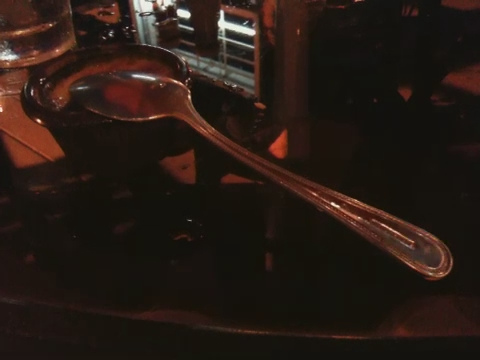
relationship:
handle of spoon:
[247, 145, 459, 286] [285, 172, 372, 221]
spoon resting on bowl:
[61, 61, 479, 285] [64, 51, 173, 68]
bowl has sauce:
[64, 51, 173, 68] [63, 65, 122, 70]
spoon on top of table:
[61, 61, 479, 285] [30, 139, 66, 158]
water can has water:
[1, 7, 74, 56] [10, 30, 49, 57]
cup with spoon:
[72, 47, 153, 67] [61, 61, 479, 285]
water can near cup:
[1, 7, 74, 56] [72, 47, 153, 67]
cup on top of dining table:
[72, 47, 153, 67] [7, 101, 32, 172]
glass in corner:
[63, 18, 77, 41] [93, 17, 123, 38]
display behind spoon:
[138, 6, 290, 66] [61, 61, 479, 285]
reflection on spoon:
[122, 71, 162, 86] [61, 61, 479, 285]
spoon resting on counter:
[61, 61, 479, 285] [73, 166, 124, 222]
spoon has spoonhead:
[61, 61, 479, 285] [68, 69, 203, 124]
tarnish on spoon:
[75, 85, 98, 104] [61, 61, 479, 285]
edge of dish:
[51, 119, 85, 133] [35, 86, 59, 116]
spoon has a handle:
[61, 61, 479, 285] [247, 145, 459, 286]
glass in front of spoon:
[63, 18, 77, 41] [61, 61, 479, 285]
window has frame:
[137, 5, 257, 41] [220, 8, 259, 25]